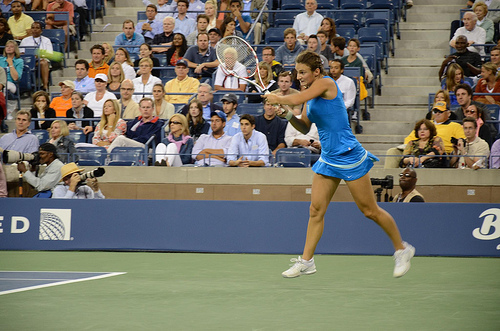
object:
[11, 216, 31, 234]
letter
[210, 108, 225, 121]
blue cap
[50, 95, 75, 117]
shirt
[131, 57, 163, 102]
person sitting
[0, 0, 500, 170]
stands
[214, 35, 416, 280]
tennis game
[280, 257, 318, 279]
shoe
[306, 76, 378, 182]
shirt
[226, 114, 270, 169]
man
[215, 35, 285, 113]
racket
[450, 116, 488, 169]
person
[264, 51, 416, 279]
woman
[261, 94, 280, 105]
hands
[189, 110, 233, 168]
man